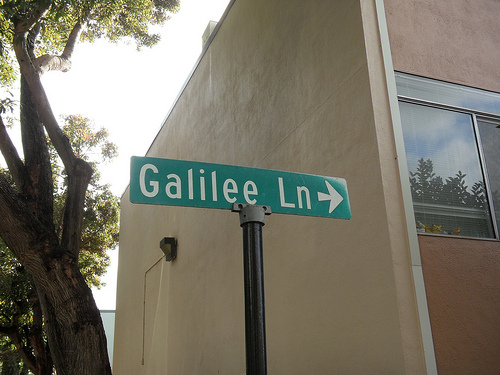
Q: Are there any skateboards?
A: No, there are no skateboards.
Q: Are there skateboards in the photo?
A: No, there are no skateboards.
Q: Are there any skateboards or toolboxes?
A: No, there are no skateboards or toolboxes.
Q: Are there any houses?
A: No, there are no houses.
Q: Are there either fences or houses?
A: No, there are no houses or fences.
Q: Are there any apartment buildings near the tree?
A: Yes, there is an apartment building near the tree.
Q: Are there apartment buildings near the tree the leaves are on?
A: Yes, there is an apartment building near the tree.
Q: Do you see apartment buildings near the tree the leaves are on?
A: Yes, there is an apartment building near the tree.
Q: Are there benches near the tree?
A: No, there is an apartment building near the tree.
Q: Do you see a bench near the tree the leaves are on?
A: No, there is an apartment building near the tree.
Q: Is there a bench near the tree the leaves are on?
A: No, there is an apartment building near the tree.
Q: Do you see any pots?
A: No, there are no pots.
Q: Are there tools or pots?
A: No, there are no pots or tools.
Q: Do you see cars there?
A: No, there are no cars.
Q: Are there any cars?
A: No, there are no cars.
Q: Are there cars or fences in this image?
A: No, there are no cars or fences.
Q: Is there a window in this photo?
A: Yes, there is a window.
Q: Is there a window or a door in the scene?
A: Yes, there is a window.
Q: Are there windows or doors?
A: Yes, there is a window.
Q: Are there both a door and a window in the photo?
A: No, there is a window but no doors.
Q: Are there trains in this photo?
A: No, there are no trains.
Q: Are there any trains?
A: No, there are no trains.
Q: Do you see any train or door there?
A: No, there are no trains or doors.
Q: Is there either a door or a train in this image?
A: No, there are no trains or doors.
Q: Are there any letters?
A: Yes, there are letters.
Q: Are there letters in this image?
A: Yes, there are letters.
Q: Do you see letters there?
A: Yes, there are letters.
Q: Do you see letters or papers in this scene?
A: Yes, there are letters.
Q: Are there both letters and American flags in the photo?
A: No, there are letters but no American flags.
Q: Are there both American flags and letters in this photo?
A: No, there are letters but no American flags.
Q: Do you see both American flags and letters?
A: No, there are letters but no American flags.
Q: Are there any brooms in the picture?
A: No, there are no brooms.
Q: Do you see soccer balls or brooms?
A: No, there are no brooms or soccer balls.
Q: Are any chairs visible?
A: No, there are no chairs.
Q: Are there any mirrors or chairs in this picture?
A: No, there are no chairs or mirrors.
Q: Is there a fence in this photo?
A: No, there are no fences.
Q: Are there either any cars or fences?
A: No, there are no fences or cars.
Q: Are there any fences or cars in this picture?
A: No, there are no fences or cars.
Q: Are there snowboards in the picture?
A: No, there are no snowboards.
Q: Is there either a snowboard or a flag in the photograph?
A: No, there are no snowboards or flags.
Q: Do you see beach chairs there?
A: No, there are no beach chairs.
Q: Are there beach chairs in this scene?
A: No, there are no beach chairs.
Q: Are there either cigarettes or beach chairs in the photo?
A: No, there are no beach chairs or cigarettes.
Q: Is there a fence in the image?
A: No, there are no fences.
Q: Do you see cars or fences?
A: No, there are no fences or cars.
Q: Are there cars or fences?
A: No, there are no fences or cars.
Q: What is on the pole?
A: The sign is on the pole.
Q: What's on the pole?
A: The sign is on the pole.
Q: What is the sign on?
A: The sign is on the pole.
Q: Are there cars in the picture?
A: No, there are no cars.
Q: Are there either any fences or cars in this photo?
A: No, there are no cars or fences.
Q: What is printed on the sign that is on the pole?
A: The arrow is printed on the sign.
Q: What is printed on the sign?
A: The arrow is printed on the sign.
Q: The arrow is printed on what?
A: The arrow is printed on the sign.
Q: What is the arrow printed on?
A: The arrow is printed on the sign.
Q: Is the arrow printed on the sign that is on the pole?
A: Yes, the arrow is printed on the sign.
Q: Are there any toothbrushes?
A: No, there are no toothbrushes.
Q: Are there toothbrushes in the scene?
A: No, there are no toothbrushes.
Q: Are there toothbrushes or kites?
A: No, there are no toothbrushes or kites.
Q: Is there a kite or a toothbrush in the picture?
A: No, there are no toothbrushes or kites.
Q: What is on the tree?
A: The leaves are on the tree.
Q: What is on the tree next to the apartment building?
A: The leaves are on the tree.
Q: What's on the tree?
A: The leaves are on the tree.